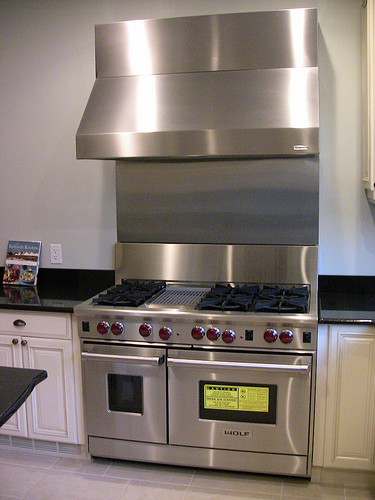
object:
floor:
[0, 433, 375, 500]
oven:
[80, 340, 317, 478]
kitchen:
[0, 0, 375, 500]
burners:
[92, 281, 167, 308]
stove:
[74, 242, 319, 478]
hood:
[76, 7, 321, 160]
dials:
[77, 312, 317, 350]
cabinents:
[0, 312, 86, 454]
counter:
[0, 283, 115, 313]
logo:
[222, 428, 252, 438]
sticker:
[204, 384, 269, 412]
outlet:
[50, 244, 63, 264]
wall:
[2, 0, 375, 277]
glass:
[107, 373, 144, 415]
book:
[3, 240, 42, 306]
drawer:
[0, 310, 72, 339]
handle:
[81, 352, 165, 366]